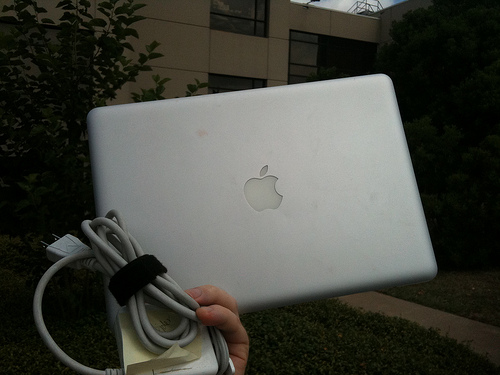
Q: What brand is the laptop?
A: Apple.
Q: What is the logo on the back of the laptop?
A: Apple.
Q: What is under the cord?
A: Post-it note.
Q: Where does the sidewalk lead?
A: Into the building.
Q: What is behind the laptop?
A: Building.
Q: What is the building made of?
A: Cement.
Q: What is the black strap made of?
A: Velcro.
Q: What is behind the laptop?
A: A bush.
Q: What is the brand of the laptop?
A: Apple.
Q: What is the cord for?
A: Charging.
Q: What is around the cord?
A: A hand.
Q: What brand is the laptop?
A: Apple.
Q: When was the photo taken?
A: Dull day.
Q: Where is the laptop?
A: In hand.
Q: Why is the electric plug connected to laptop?
A: Connect to source of power.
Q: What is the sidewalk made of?
A: Concrete.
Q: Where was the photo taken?
A: In front of building.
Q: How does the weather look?
A: Dull.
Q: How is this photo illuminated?
A: Sunlight.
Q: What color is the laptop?
A: Silver.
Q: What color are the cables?
A: Gray.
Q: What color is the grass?
A: Green.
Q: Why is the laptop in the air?
A: It is being held.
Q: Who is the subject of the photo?
A: The laptop.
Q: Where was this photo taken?
A: Outside a building.